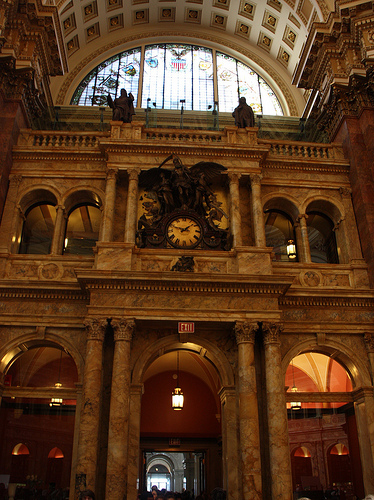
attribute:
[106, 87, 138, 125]
statue — standing high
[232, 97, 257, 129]
statue — standing high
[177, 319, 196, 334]
sign — red, white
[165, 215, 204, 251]
clock — large, white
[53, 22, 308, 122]
window — stained glass, arched, here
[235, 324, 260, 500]
column — marble, marbled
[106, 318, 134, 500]
column — marble, marbled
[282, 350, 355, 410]
canopy — orange, white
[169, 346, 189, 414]
light — hanging, illuminated, on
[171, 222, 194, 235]
hands — black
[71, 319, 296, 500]
columns — marble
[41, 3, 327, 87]
ceiling — decorative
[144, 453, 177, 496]
doorway — arched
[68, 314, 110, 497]
column — marbled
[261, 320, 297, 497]
column — marbled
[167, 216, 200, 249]
numbers — roman